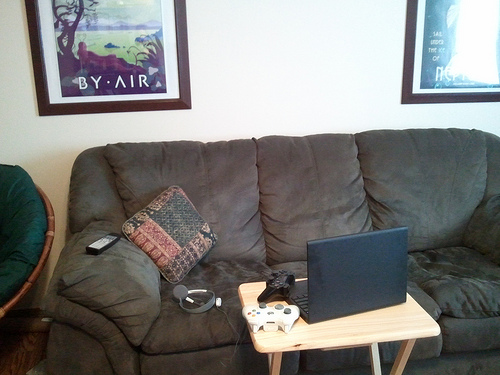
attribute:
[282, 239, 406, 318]
laptop — open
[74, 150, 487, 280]
couch — brown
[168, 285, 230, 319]
headphones — gray